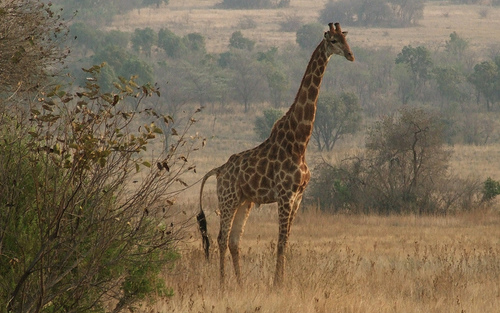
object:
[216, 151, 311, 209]
lines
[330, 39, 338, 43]
eye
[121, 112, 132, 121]
leaf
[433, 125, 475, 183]
wall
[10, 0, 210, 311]
foliage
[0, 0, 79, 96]
bushes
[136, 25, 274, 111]
trees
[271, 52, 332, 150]
neck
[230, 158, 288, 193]
spots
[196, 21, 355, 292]
giraffe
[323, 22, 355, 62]
giraffe head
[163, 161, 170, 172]
leaf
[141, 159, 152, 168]
leaf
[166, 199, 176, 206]
leaf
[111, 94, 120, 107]
leaf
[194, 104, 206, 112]
leaf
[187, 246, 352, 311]
grass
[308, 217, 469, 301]
plains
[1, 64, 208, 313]
bush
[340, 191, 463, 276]
grass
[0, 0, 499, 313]
field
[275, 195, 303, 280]
legs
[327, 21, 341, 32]
ossicones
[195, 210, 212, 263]
tuft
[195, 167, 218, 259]
tail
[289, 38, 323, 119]
mane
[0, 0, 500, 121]
distance